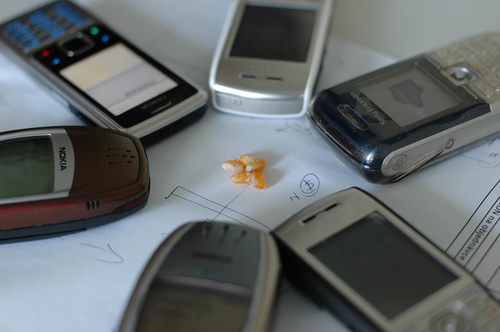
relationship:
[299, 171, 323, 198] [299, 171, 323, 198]
sign for sign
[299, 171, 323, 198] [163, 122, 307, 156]
sign on paper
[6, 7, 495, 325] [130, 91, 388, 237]
phones in a circle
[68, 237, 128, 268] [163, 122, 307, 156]
arrow on paper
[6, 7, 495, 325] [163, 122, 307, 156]
phones on paper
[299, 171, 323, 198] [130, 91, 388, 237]
sign in a circle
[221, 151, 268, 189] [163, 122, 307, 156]
kernels on paper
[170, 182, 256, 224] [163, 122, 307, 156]
lines on paper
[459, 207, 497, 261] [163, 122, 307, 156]
words on paper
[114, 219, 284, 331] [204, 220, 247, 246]
phone has holes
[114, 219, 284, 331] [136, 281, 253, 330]
phone has a screen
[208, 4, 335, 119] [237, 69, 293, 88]
mobile has earpiece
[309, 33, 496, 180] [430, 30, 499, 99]
phone has keypad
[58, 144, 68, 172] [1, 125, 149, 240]
nokia on phone